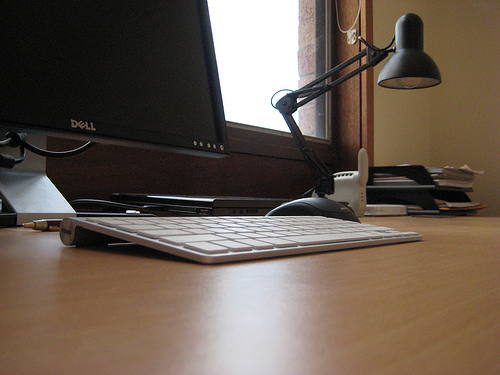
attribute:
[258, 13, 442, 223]
lamp — closed, black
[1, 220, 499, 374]
desk — wooden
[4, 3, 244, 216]
computer — monitor, black, dell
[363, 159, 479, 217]
rack — black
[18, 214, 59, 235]
pen — writing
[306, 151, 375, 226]
modem — white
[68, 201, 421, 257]
keyboard — white, whiet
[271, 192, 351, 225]
mouse — black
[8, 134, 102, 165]
wires — black